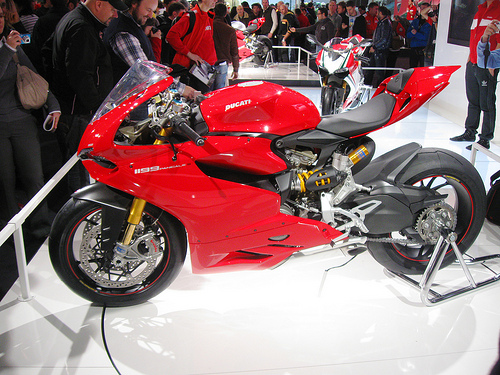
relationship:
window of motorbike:
[79, 50, 182, 138] [105, 116, 387, 294]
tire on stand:
[365, 145, 490, 275] [396, 235, 496, 312]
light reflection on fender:
[22, 134, 157, 254] [74, 187, 117, 217]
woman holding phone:
[0, 6, 74, 243] [18, 115, 31, 130]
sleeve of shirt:
[104, 99, 154, 113] [112, 51, 157, 70]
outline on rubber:
[64, 226, 73, 267] [61, 204, 165, 319]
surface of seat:
[305, 74, 419, 147] [324, 103, 384, 119]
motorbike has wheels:
[45, 58, 488, 308] [63, 164, 444, 317]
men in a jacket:
[108, 0, 201, 101] [240, 100, 277, 104]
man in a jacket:
[447, 0, 500, 151] [467, 108, 482, 121]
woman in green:
[0, 6, 74, 243] [44, 151, 69, 157]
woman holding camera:
[0, 6, 74, 243] [19, 130, 61, 169]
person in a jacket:
[219, 51, 254, 56] [271, 105, 310, 122]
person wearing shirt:
[395, 0, 432, 76] [402, 12, 436, 58]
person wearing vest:
[246, 7, 278, 44] [254, 5, 275, 35]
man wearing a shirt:
[45, 1, 133, 195] [43, 8, 128, 133]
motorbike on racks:
[45, 25, 495, 301] [6, 74, 497, 372]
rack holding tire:
[372, 222, 495, 302] [365, 135, 483, 281]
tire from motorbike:
[365, 135, 483, 281] [45, 25, 495, 301]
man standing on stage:
[449, 21, 498, 150] [7, 79, 494, 369]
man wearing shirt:
[447, 0, 497, 158] [463, 6, 497, 68]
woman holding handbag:
[0, 22, 72, 240] [13, 62, 57, 115]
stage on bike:
[7, 79, 494, 369] [37, 14, 497, 321]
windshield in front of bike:
[89, 54, 169, 124] [45, 30, 486, 309]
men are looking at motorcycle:
[78, 2, 168, 62] [307, 30, 381, 107]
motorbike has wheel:
[45, 58, 488, 308] [42, 179, 191, 317]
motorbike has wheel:
[45, 58, 488, 308] [359, 137, 489, 280]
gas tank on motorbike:
[193, 72, 327, 144] [45, 58, 488, 308]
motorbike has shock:
[45, 58, 488, 308] [122, 197, 147, 242]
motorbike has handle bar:
[45, 58, 488, 308] [172, 106, 212, 151]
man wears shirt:
[447, 0, 500, 151] [466, 1, 500, 68]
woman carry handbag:
[0, 6, 74, 243] [13, 51, 50, 111]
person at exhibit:
[406, 0, 433, 68] [4, 3, 498, 373]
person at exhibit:
[259, 1, 280, 42] [4, 3, 498, 373]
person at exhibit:
[335, 1, 369, 39] [4, 3, 498, 373]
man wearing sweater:
[161, 5, 222, 92] [165, 4, 220, 70]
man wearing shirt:
[45, 1, 133, 195] [48, 3, 129, 117]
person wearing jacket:
[406, 0, 433, 68] [407, 17, 434, 46]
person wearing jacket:
[208, 3, 241, 91] [210, 20, 240, 65]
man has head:
[45, 1, 133, 195] [73, 1, 126, 27]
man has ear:
[45, 1, 133, 150] [89, 1, 113, 13]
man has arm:
[45, 1, 133, 150] [62, 20, 100, 114]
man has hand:
[166, 1, 219, 94] [185, 49, 206, 65]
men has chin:
[108, 0, 201, 101] [136, 14, 149, 27]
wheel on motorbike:
[44, 181, 188, 305] [45, 58, 488, 308]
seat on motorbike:
[312, 58, 459, 138] [45, 58, 488, 308]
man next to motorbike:
[45, 1, 133, 195] [45, 58, 488, 308]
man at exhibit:
[45, 1, 133, 195] [4, 3, 498, 373]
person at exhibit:
[368, 1, 398, 77] [4, 3, 498, 373]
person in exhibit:
[255, 1, 283, 61] [4, 3, 498, 373]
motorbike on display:
[45, 58, 488, 308] [20, 21, 483, 361]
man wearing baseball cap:
[45, 1, 133, 150] [100, 2, 138, 20]